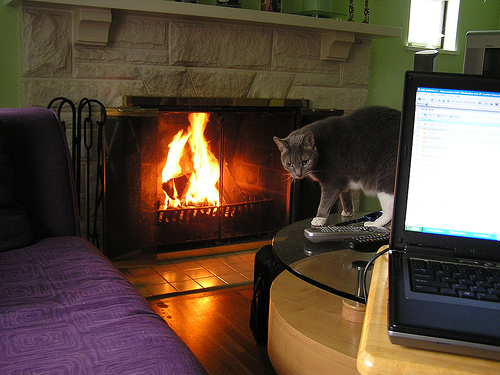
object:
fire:
[161, 112, 223, 205]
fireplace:
[123, 98, 294, 246]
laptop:
[387, 69, 499, 362]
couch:
[0, 108, 210, 374]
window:
[407, 0, 447, 48]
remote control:
[303, 224, 382, 238]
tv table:
[356, 240, 498, 373]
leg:
[373, 190, 396, 225]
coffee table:
[270, 208, 391, 306]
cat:
[273, 104, 399, 226]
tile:
[144, 282, 177, 299]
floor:
[118, 248, 279, 374]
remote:
[344, 233, 389, 249]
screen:
[401, 86, 499, 241]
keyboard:
[407, 257, 499, 302]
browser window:
[403, 88, 500, 241]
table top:
[272, 215, 392, 302]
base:
[268, 249, 373, 373]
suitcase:
[250, 242, 288, 349]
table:
[268, 213, 378, 374]